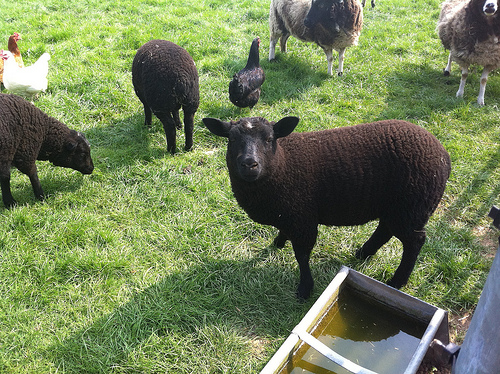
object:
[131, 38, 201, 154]
black sheep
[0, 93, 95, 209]
black sheep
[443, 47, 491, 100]
legs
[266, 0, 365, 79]
sheep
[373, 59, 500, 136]
shadow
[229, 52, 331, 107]
shadow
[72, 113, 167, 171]
shadow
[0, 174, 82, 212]
shadow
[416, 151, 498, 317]
shadow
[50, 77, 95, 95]
shadow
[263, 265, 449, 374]
trough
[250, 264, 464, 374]
fence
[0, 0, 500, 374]
grass field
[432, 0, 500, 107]
sheep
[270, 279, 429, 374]
water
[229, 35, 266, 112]
chicken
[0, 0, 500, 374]
grass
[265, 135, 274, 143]
eye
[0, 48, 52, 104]
chicken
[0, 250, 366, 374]
shadow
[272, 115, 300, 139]
ear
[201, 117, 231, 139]
ear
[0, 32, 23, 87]
chicken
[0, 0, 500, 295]
animals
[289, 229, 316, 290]
leg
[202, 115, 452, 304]
black sheep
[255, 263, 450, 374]
bin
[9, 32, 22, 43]
head